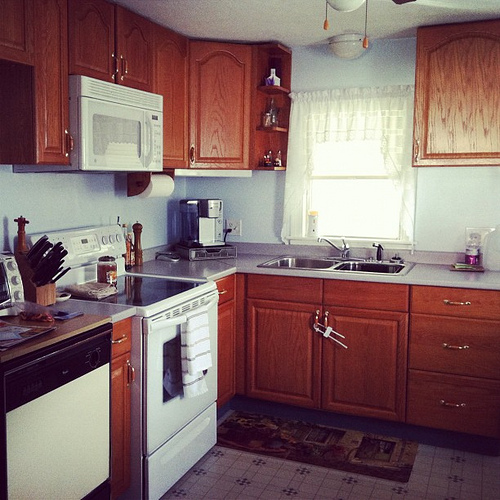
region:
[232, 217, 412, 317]
Sink in the kitchen.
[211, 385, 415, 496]
Rug on the floor.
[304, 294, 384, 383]
Lock on the cabinet.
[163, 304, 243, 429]
Towel on the stove.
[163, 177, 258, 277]
Coffee maker on the counter.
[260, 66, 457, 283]
Window on the wall.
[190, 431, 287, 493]
Tile on the floor.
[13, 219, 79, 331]
Knives on the counter.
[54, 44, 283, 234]
Microwave in the cabinet.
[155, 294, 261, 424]
Stripes on the towel.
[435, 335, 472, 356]
handle on a drawer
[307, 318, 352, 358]
white lock on door handles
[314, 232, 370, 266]
faucet on a sink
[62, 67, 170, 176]
microwave oven in a kitchen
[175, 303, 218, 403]
towel on a range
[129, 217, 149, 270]
pepper on a kitchen counter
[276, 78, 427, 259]
window above a kitchen sink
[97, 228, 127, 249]
knobs on an oven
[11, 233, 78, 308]
knives on a kitchen counter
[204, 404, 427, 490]
carpet on a floor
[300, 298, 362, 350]
brown cabinet with lock on it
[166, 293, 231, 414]
oven handle with white towel on it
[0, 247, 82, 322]
wooden knife rack with black knives in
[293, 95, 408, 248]
white window with white cloth hanging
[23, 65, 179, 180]
white microwave with vent on it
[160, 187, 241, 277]
coffee maker without the coffee pot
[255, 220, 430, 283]
two basket sink that is silver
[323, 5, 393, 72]
ceiling fan with two strings with wooden knob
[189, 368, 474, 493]
floor mat with windows and houses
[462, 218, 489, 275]
dish soap that is purple and circular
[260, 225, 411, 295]
a stainless steel kitchen sink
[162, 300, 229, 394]
towel hanging on the stove handle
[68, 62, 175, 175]
microwave above the stove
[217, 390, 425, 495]
rug on the floor in front of the sink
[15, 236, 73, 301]
knife holder on the counter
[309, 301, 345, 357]
lock on the kitchen cabinet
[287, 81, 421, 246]
window above the kitchen sink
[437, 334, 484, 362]
handle on the drawer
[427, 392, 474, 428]
handle on the drawer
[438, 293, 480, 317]
handle on the drawer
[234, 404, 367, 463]
small brown runner on the floor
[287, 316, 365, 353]
silver lock on the cabinet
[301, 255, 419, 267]
pair of silver sinks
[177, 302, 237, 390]
white table cloth on stove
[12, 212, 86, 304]
block of black butcher knives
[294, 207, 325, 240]
white soap dispenser on window sill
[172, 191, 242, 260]
large silver coffee maker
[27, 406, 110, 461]
white cover on dish washer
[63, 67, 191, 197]
white microwave in the cabinets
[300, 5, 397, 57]
cords in the ceiling